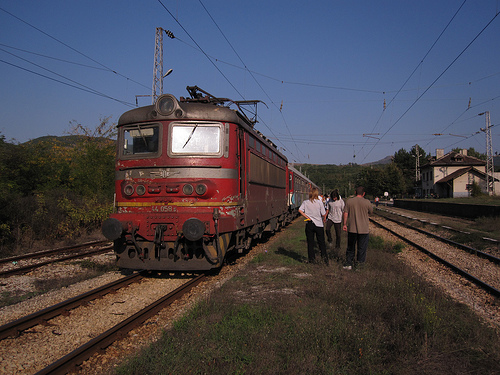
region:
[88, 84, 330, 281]
Long train in a field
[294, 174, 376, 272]
People close to the train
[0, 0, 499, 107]
Wires running above the train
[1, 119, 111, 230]
Plants on the left side of the train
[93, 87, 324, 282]
Train is red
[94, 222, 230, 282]
Train bumpers are black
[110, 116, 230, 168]
Two front windows in the train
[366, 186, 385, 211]
Person walking near train rails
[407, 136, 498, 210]
Houses on left side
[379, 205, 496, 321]
Rails on left side of the road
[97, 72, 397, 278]
people standing beside a train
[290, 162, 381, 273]
people in black pants on grass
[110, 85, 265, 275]
weathered surface of train engine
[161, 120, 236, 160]
windshield reflecting light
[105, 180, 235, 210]
yellow stripe under lights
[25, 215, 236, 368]
tracks and gravel in front of train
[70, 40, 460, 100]
wires overhead above tracks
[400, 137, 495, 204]
brown and white building by tracks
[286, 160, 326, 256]
person reaching under shirt hem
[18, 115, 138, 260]
grassy hill on side of train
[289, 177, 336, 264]
woman in white shirt and black pants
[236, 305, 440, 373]
grass and foliage is green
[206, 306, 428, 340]
grass and foliage is green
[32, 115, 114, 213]
grass and foliage is green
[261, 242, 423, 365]
grass and foliage is green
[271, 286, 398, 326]
grass and foliage is green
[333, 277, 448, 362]
grass and foliage is green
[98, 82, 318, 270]
old rusty train is parked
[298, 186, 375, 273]
people stand next to train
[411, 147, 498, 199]
house next to tracks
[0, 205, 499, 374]
multiple sets of tracks under and near train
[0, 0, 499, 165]
sky is blue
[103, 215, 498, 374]
patch of grass under people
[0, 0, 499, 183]
wires above train and people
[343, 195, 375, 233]
man wearing tan shirt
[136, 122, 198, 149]
two windshield wipers on front of train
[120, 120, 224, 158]
two windows on front of train